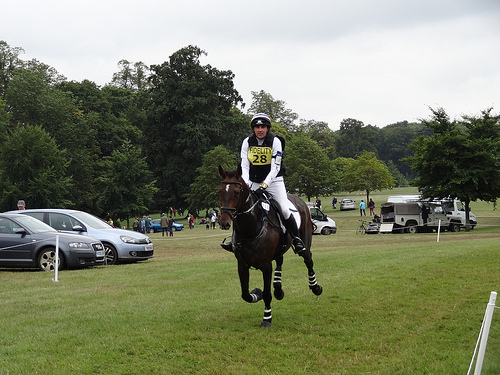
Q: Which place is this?
A: It is a field.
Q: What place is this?
A: It is a field.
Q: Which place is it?
A: It is a field.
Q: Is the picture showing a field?
A: Yes, it is showing a field.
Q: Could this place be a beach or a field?
A: It is a field.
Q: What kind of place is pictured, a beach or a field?
A: It is a field.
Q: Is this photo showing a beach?
A: No, the picture is showing a field.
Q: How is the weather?
A: It is cloudy.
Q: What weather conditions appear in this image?
A: It is cloudy.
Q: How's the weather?
A: It is cloudy.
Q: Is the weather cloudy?
A: Yes, it is cloudy.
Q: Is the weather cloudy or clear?
A: It is cloudy.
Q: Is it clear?
A: No, it is cloudy.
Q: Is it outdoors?
A: Yes, it is outdoors.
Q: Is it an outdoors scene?
A: Yes, it is outdoors.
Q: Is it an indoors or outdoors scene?
A: It is outdoors.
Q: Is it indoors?
A: No, it is outdoors.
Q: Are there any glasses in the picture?
A: No, there are no glasses.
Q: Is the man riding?
A: Yes, the man is riding.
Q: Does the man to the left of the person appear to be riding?
A: Yes, the man is riding.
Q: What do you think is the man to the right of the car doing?
A: The man is riding.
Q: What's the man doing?
A: The man is riding.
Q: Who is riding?
A: The man is riding.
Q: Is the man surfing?
A: No, the man is riding.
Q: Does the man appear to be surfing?
A: No, the man is riding.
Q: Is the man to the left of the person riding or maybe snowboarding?
A: The man is riding.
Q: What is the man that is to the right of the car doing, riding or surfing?
A: The man is riding.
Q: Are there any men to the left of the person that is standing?
A: Yes, there is a man to the left of the person.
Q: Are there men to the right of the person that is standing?
A: No, the man is to the left of the person.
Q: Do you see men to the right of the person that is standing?
A: No, the man is to the left of the person.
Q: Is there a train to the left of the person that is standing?
A: No, there is a man to the left of the person.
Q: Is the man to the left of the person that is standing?
A: Yes, the man is to the left of the person.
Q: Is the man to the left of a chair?
A: No, the man is to the left of the person.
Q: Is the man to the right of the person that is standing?
A: No, the man is to the left of the person.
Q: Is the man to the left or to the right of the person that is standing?
A: The man is to the left of the person.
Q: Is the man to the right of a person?
A: No, the man is to the left of a person.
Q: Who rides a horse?
A: The man rides a horse.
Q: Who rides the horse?
A: The man rides a horse.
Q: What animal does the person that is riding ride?
A: The man rides a horse.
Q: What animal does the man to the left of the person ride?
A: The man rides a horse.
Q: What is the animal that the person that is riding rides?
A: The animal is a horse.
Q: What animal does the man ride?
A: The man rides a horse.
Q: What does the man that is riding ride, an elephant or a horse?
A: The man rides a horse.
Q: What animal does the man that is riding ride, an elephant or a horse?
A: The man rides a horse.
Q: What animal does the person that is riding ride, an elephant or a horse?
A: The man rides a horse.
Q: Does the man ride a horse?
A: Yes, the man rides a horse.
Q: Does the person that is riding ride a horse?
A: Yes, the man rides a horse.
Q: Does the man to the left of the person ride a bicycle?
A: No, the man rides a horse.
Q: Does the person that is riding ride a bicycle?
A: No, the man rides a horse.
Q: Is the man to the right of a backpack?
A: No, the man is to the right of the car.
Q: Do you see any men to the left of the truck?
A: Yes, there is a man to the left of the truck.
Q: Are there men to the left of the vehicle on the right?
A: Yes, there is a man to the left of the truck.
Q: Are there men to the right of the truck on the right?
A: No, the man is to the left of the truck.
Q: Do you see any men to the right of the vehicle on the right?
A: No, the man is to the left of the truck.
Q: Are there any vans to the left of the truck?
A: No, there is a man to the left of the truck.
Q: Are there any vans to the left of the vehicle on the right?
A: No, there is a man to the left of the truck.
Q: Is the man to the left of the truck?
A: Yes, the man is to the left of the truck.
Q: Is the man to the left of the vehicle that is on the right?
A: Yes, the man is to the left of the truck.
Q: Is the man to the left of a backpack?
A: No, the man is to the left of the truck.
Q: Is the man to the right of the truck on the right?
A: No, the man is to the left of the truck.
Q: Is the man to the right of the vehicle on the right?
A: No, the man is to the left of the truck.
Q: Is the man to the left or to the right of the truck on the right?
A: The man is to the left of the truck.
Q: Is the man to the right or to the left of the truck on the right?
A: The man is to the left of the truck.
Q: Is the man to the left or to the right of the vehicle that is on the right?
A: The man is to the left of the truck.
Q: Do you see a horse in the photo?
A: Yes, there is a horse.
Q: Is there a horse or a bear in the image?
A: Yes, there is a horse.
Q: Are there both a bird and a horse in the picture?
A: No, there is a horse but no birds.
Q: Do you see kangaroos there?
A: No, there are no kangaroos.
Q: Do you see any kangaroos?
A: No, there are no kangaroos.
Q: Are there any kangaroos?
A: No, there are no kangaroos.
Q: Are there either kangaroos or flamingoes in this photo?
A: No, there are no kangaroos or flamingoes.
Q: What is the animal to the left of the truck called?
A: The animal is a horse.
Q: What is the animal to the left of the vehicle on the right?
A: The animal is a horse.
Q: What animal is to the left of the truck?
A: The animal is a horse.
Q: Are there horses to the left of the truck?
A: Yes, there is a horse to the left of the truck.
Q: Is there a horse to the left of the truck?
A: Yes, there is a horse to the left of the truck.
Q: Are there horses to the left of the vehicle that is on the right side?
A: Yes, there is a horse to the left of the truck.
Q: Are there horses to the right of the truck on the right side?
A: No, the horse is to the left of the truck.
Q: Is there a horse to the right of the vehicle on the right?
A: No, the horse is to the left of the truck.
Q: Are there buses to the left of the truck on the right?
A: No, there is a horse to the left of the truck.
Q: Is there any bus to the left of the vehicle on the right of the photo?
A: No, there is a horse to the left of the truck.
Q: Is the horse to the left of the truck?
A: Yes, the horse is to the left of the truck.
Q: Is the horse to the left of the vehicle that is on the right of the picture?
A: Yes, the horse is to the left of the truck.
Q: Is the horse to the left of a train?
A: No, the horse is to the left of the truck.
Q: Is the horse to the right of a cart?
A: No, the horse is to the right of the car.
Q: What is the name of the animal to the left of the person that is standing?
A: The animal is a horse.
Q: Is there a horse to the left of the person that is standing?
A: Yes, there is a horse to the left of the person.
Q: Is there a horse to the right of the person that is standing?
A: No, the horse is to the left of the person.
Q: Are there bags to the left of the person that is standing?
A: No, there is a horse to the left of the person.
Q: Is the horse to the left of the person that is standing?
A: Yes, the horse is to the left of the person.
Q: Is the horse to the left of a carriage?
A: No, the horse is to the left of the person.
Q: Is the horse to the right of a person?
A: No, the horse is to the left of a person.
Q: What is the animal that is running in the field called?
A: The animal is a horse.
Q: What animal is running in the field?
A: The animal is a horse.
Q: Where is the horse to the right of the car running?
A: The horse is running in the field.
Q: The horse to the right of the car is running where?
A: The horse is running in the field.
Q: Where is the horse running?
A: The horse is running in the field.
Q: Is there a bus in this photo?
A: No, there are no buses.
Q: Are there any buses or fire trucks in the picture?
A: No, there are no buses or fire trucks.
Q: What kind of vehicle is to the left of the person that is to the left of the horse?
A: The vehicle is a car.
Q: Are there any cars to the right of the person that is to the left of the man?
A: No, the car is to the left of the person.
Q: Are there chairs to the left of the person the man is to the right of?
A: No, there is a car to the left of the person.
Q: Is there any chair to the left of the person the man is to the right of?
A: No, there is a car to the left of the person.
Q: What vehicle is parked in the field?
A: The vehicle is a car.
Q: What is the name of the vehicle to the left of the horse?
A: The vehicle is a car.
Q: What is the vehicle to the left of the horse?
A: The vehicle is a car.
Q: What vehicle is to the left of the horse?
A: The vehicle is a car.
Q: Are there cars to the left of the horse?
A: Yes, there is a car to the left of the horse.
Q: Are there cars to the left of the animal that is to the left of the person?
A: Yes, there is a car to the left of the horse.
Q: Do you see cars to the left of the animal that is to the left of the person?
A: Yes, there is a car to the left of the horse.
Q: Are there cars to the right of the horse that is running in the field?
A: No, the car is to the left of the horse.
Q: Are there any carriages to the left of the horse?
A: No, there is a car to the left of the horse.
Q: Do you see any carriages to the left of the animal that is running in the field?
A: No, there is a car to the left of the horse.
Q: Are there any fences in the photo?
A: Yes, there is a fence.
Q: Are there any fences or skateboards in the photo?
A: Yes, there is a fence.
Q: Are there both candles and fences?
A: No, there is a fence but no candles.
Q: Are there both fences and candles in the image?
A: No, there is a fence but no candles.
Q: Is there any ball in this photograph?
A: No, there are no balls.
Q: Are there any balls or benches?
A: No, there are no balls or benches.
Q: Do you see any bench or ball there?
A: No, there are no balls or benches.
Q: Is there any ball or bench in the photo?
A: No, there are no balls or benches.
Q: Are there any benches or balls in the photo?
A: No, there are no balls or benches.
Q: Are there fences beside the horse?
A: Yes, there is a fence beside the horse.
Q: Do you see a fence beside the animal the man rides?
A: Yes, there is a fence beside the horse.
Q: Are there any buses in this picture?
A: No, there are no buses.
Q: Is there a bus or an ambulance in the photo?
A: No, there are no buses or ambulances.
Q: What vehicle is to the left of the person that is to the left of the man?
A: The vehicle is a car.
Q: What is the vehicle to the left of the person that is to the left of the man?
A: The vehicle is a car.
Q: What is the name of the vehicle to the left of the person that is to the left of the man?
A: The vehicle is a car.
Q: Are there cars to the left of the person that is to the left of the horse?
A: Yes, there is a car to the left of the person.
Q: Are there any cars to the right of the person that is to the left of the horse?
A: No, the car is to the left of the person.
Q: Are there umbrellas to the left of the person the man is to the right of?
A: No, there is a car to the left of the person.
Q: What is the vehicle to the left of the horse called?
A: The vehicle is a car.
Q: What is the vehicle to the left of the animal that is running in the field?
A: The vehicle is a car.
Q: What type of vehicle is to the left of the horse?
A: The vehicle is a car.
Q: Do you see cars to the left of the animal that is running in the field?
A: Yes, there is a car to the left of the horse.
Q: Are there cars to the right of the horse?
A: No, the car is to the left of the horse.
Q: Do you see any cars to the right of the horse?
A: No, the car is to the left of the horse.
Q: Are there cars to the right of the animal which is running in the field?
A: No, the car is to the left of the horse.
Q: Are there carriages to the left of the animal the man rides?
A: No, there is a car to the left of the horse.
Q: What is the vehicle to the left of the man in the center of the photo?
A: The vehicle is a car.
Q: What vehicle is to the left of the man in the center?
A: The vehicle is a car.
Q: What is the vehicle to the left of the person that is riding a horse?
A: The vehicle is a car.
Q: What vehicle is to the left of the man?
A: The vehicle is a car.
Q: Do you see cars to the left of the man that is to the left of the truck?
A: Yes, there is a car to the left of the man.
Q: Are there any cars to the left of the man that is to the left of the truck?
A: Yes, there is a car to the left of the man.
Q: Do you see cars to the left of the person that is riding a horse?
A: Yes, there is a car to the left of the man.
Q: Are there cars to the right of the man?
A: No, the car is to the left of the man.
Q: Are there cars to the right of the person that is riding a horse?
A: No, the car is to the left of the man.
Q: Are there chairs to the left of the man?
A: No, there is a car to the left of the man.